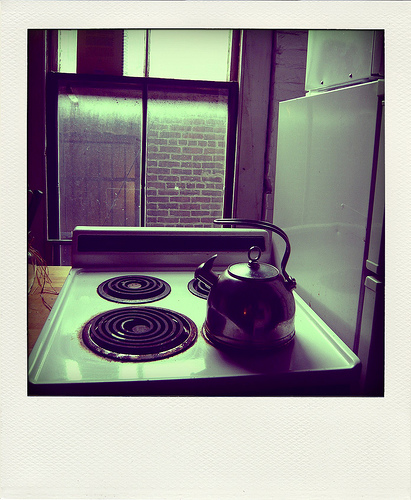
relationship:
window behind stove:
[46, 30, 230, 239] [27, 226, 360, 381]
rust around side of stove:
[96, 341, 155, 420] [35, 230, 364, 393]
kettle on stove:
[193, 212, 305, 365] [43, 224, 331, 391]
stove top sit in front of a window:
[48, 242, 324, 373] [56, 83, 233, 215]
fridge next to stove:
[354, 307, 375, 335] [34, 75, 378, 380]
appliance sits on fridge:
[304, 29, 384, 97] [270, 78, 383, 385]